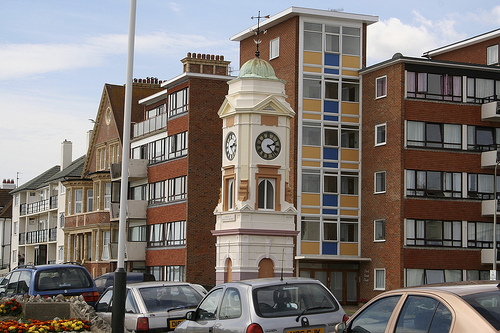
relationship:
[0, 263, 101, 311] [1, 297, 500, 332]
van parked on road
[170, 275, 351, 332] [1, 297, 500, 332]
car parked on road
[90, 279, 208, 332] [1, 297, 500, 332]
car on road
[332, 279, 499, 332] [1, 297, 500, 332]
car parked on road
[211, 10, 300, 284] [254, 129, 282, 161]
tower has a clock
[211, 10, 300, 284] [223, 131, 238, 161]
tower has a clock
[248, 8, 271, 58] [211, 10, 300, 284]
vane atop tower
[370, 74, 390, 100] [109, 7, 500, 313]
window on building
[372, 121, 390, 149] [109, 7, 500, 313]
window on building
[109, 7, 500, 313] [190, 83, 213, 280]
building made of bricks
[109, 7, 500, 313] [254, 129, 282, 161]
building has clock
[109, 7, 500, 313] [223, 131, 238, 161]
building has a clock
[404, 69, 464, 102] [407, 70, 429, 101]
windows have curtains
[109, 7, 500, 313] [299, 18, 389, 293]
building has many windows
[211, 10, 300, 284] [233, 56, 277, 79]
tower has top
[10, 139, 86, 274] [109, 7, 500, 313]
building behind building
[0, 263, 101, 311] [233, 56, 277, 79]
van at top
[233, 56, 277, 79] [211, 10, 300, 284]
top of tower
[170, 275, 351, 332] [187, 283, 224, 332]
car has door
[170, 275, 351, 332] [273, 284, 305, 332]
car has a door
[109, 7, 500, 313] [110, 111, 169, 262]
building has balconies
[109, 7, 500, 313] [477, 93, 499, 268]
building has balconies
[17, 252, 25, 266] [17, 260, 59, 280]
person on a balcony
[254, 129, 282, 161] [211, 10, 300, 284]
clock on tower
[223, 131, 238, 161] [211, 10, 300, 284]
clock on tower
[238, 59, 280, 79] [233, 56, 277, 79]
dome on top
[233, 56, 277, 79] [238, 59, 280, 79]
top of dome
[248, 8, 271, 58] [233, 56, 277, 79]
vane on top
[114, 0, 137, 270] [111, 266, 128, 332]
pole on base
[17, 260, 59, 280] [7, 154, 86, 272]
balcony on building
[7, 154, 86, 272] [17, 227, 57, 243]
building with fence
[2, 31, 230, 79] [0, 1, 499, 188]
cloud in sky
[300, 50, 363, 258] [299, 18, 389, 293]
facade has windows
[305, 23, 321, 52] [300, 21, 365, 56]
curtain in window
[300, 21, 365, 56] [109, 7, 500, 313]
window of building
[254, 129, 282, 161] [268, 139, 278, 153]
clock has hands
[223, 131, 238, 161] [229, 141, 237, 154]
clock has hands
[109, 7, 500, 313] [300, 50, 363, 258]
building has facade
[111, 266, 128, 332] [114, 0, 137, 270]
base of pole